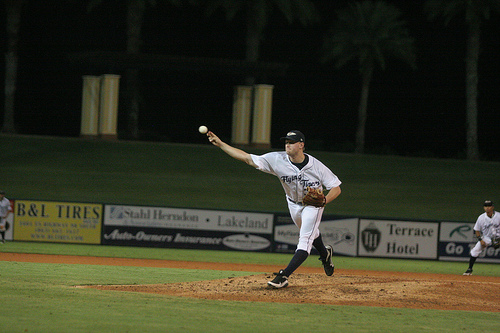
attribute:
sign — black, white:
[102, 205, 274, 249]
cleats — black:
[265, 243, 335, 290]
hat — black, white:
[272, 125, 314, 147]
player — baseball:
[193, 123, 369, 297]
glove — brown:
[305, 187, 327, 207]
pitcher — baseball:
[207, 115, 347, 290]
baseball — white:
[197, 123, 207, 133]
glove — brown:
[301, 183, 327, 205]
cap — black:
[279, 113, 309, 138]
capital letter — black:
[383, 240, 399, 258]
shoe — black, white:
[266, 271, 288, 292]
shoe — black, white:
[321, 243, 336, 277]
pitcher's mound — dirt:
[137, 265, 499, 312]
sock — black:
[276, 248, 308, 276]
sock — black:
[310, 235, 325, 257]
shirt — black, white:
[247, 151, 347, 201]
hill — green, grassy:
[14, 127, 480, 235]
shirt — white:
[253, 151, 336, 202]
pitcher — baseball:
[193, 122, 343, 292]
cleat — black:
[262, 272, 293, 290]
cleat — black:
[319, 245, 339, 281]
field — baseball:
[0, 239, 497, 330]